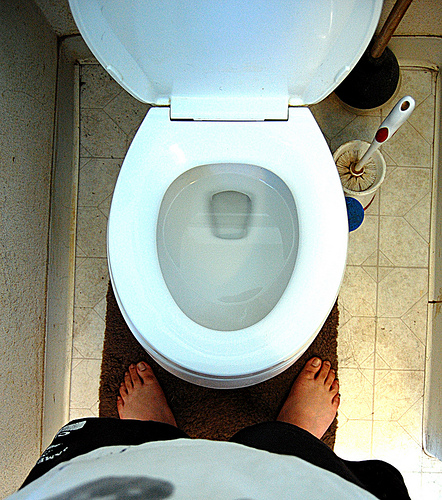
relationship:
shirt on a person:
[36, 462, 332, 500] [115, 374, 349, 493]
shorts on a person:
[48, 418, 167, 446] [36, 442, 323, 500]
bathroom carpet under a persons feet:
[98, 281, 339, 455] [99, 355, 363, 467]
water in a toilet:
[160, 188, 286, 309] [133, 188, 348, 403]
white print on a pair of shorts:
[26, 407, 86, 500] [42, 410, 330, 450]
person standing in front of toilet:
[2, 357, 411, 498] [65, 0, 387, 390]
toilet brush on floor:
[336, 93, 415, 193] [67, 64, 439, 497]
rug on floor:
[98, 278, 343, 456] [67, 64, 439, 497]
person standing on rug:
[2, 357, 411, 498] [98, 278, 343, 456]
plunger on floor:
[335, 1, 419, 111] [68, 65, 434, 460]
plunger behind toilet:
[335, 1, 419, 111] [65, 0, 387, 390]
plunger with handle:
[335, 1, 419, 111] [372, 1, 411, 59]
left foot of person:
[114, 360, 178, 429] [2, 357, 411, 498]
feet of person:
[278, 358, 340, 440] [2, 357, 411, 498]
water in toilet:
[160, 188, 286, 309] [84, 39, 379, 393]